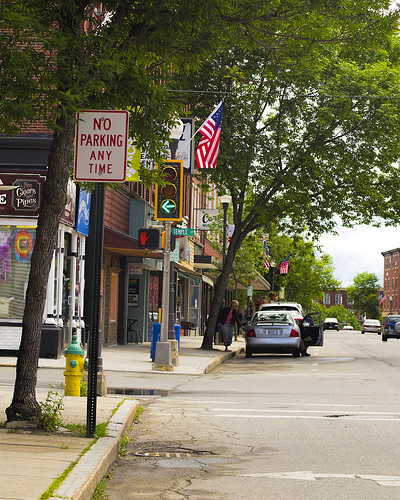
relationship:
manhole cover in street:
[134, 439, 198, 464] [102, 319, 399, 500]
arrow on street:
[244, 461, 398, 498] [102, 319, 399, 500]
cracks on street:
[140, 398, 222, 499] [102, 319, 399, 500]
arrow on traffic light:
[162, 200, 178, 218] [150, 157, 186, 225]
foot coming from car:
[301, 352, 316, 361] [245, 308, 339, 362]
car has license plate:
[245, 308, 339, 362] [266, 328, 279, 336]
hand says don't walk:
[139, 230, 151, 249] [139, 229, 164, 254]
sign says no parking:
[74, 107, 132, 185] [82, 117, 124, 149]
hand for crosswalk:
[139, 230, 151, 249] [151, 396, 399, 424]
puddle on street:
[106, 376, 169, 403] [102, 319, 399, 500]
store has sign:
[2, 135, 108, 367] [8, 176, 44, 225]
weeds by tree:
[37, 389, 69, 432] [8, 0, 240, 427]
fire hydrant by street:
[61, 333, 87, 398] [102, 319, 399, 500]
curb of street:
[47, 396, 143, 499] [102, 319, 399, 500]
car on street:
[245, 308, 339, 362] [102, 319, 399, 500]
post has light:
[150, 154, 187, 374] [157, 114, 187, 147]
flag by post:
[194, 102, 228, 174] [150, 154, 187, 374]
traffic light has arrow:
[150, 157, 186, 225] [162, 200, 178, 218]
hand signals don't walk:
[139, 230, 151, 249] [139, 229, 164, 254]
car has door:
[245, 308, 339, 362] [299, 308, 326, 349]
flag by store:
[194, 102, 228, 174] [2, 135, 108, 367]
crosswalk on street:
[151, 396, 399, 424] [102, 319, 399, 500]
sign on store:
[76, 187, 95, 238] [2, 135, 108, 367]